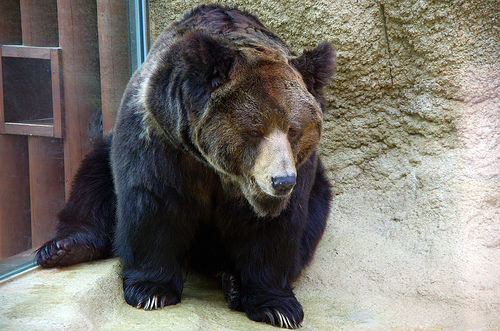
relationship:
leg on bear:
[111, 185, 191, 309] [161, 23, 324, 253]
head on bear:
[175, 36, 337, 218] [34, 4, 332, 328]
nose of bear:
[266, 174, 301, 196] [34, 4, 332, 328]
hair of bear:
[32, 2, 333, 330] [34, 4, 332, 328]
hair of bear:
[240, 45, 306, 124] [34, 4, 332, 328]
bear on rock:
[34, 4, 332, 328] [146, 0, 498, 330]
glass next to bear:
[15, 10, 95, 136] [34, 4, 332, 328]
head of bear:
[175, 36, 337, 218] [34, 4, 332, 328]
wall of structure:
[1, 3, 132, 263] [9, 9, 100, 139]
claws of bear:
[141, 298, 159, 308] [149, 23, 342, 246]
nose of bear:
[273, 177, 297, 189] [34, 4, 332, 328]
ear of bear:
[178, 27, 237, 83] [34, 4, 332, 328]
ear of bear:
[290, 46, 331, 105] [34, 4, 332, 328]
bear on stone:
[34, 4, 332, 328] [369, 112, 469, 305]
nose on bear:
[273, 177, 297, 189] [34, 4, 332, 328]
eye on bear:
[238, 122, 263, 146] [34, 4, 332, 328]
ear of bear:
[177, 29, 237, 78] [34, 4, 332, 328]